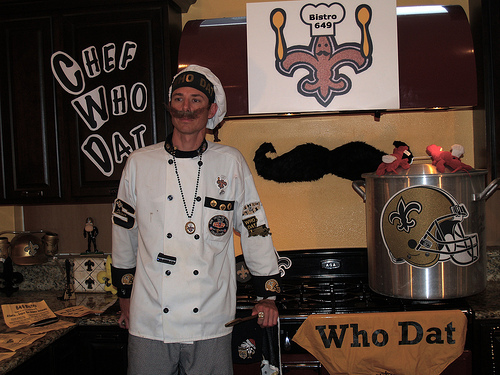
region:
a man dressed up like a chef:
[108, 62, 280, 373]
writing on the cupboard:
[48, 39, 148, 175]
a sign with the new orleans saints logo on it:
[242, 0, 400, 113]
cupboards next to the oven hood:
[2, 6, 155, 212]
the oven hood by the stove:
[183, 2, 486, 112]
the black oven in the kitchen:
[231, 251, 472, 373]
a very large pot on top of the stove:
[357, 149, 499, 298]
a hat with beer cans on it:
[0, 226, 60, 266]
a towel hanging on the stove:
[294, 312, 471, 372]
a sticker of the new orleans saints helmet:
[373, 186, 477, 272]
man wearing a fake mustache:
[108, 62, 279, 373]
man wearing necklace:
[172, 143, 209, 235]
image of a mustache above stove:
[255, 137, 411, 185]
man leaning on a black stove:
[233, 246, 491, 372]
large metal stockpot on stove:
[350, 155, 496, 305]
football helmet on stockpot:
[376, 183, 477, 264]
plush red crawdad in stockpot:
[423, 142, 471, 170]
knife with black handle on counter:
[5, 312, 60, 332]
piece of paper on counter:
[53, 297, 110, 318]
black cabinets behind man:
[1, 0, 173, 205]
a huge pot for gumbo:
[350, 146, 495, 298]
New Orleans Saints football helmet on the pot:
[380, 181, 478, 269]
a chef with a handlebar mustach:
[167, 62, 223, 148]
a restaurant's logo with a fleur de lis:
[258, 0, 389, 100]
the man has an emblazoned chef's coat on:
[110, 135, 278, 345]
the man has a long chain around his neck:
[165, 133, 205, 234]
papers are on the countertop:
[0, 290, 127, 365]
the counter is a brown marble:
[1, 248, 129, 373]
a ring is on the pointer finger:
[247, 300, 277, 330]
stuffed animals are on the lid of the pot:
[364, 137, 481, 179]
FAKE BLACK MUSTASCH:
[168, 102, 209, 121]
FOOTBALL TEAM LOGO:
[373, 187, 479, 268]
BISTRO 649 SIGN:
[258, 1, 381, 106]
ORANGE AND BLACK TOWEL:
[311, 312, 464, 353]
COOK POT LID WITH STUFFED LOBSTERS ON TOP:
[371, 141, 483, 179]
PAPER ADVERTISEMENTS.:
[7, 303, 93, 351]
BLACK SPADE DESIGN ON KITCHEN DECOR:
[76, 257, 108, 292]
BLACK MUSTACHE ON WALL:
[251, 132, 443, 192]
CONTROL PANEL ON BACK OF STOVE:
[299, 249, 362, 307]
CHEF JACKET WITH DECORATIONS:
[96, 140, 281, 334]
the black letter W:
[309, 319, 351, 356]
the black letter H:
[349, 320, 371, 352]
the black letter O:
[368, 323, 393, 350]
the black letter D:
[397, 317, 424, 349]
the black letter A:
[422, 322, 446, 352]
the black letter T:
[441, 317, 464, 351]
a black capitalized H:
[99, 77, 136, 119]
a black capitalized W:
[314, 324, 351, 351]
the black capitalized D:
[391, 310, 426, 350]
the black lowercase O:
[371, 329, 388, 347]